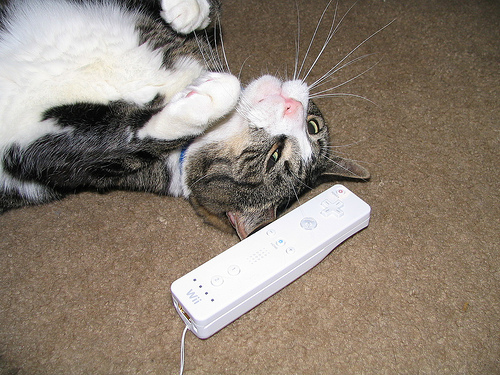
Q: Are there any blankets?
A: No, there are no blankets.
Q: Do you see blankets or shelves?
A: No, there are no blankets or shelves.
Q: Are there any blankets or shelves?
A: No, there are no blankets or shelves.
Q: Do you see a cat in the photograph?
A: Yes, there is a cat.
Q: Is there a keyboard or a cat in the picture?
A: Yes, there is a cat.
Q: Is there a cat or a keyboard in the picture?
A: Yes, there is a cat.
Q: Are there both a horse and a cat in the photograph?
A: No, there is a cat but no horses.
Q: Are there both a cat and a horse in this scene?
A: No, there is a cat but no horses.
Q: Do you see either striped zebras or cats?
A: Yes, there is a striped cat.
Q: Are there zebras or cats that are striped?
A: Yes, the cat is striped.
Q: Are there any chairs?
A: No, there are no chairs.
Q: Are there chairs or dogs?
A: No, there are no chairs or dogs.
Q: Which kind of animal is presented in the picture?
A: The animal is a cat.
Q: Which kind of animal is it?
A: The animal is a cat.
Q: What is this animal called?
A: That is a cat.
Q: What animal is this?
A: That is a cat.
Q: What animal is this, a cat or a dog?
A: That is a cat.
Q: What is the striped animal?
A: The animal is a cat.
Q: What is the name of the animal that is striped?
A: The animal is a cat.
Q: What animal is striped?
A: The animal is a cat.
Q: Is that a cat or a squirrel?
A: That is a cat.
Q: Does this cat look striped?
A: Yes, the cat is striped.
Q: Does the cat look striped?
A: Yes, the cat is striped.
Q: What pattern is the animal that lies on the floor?
A: The cat is striped.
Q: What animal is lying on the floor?
A: The cat is lying on the floor.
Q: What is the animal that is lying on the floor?
A: The animal is a cat.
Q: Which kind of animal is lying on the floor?
A: The animal is a cat.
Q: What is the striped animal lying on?
A: The cat is lying on the floor.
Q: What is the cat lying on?
A: The cat is lying on the floor.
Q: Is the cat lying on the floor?
A: Yes, the cat is lying on the floor.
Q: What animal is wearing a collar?
A: The cat is wearing a collar.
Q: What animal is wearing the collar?
A: The cat is wearing a collar.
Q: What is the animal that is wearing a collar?
A: The animal is a cat.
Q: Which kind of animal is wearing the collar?
A: The animal is a cat.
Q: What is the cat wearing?
A: The cat is wearing a collar.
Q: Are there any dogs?
A: No, there are no dogs.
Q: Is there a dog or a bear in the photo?
A: No, there are no dogs or bears.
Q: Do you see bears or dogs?
A: No, there are no dogs or bears.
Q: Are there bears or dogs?
A: No, there are no dogs or bears.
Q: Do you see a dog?
A: No, there are no dogs.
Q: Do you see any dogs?
A: No, there are no dogs.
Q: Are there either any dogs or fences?
A: No, there are no dogs or fences.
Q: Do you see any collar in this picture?
A: Yes, there is a collar.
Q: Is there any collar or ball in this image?
A: Yes, there is a collar.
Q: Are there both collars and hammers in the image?
A: No, there is a collar but no hammers.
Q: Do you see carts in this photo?
A: No, there are no carts.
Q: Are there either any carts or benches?
A: No, there are no carts or benches.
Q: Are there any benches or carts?
A: No, there are no carts or benches.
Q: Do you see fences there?
A: No, there are no fences.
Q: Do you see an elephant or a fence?
A: No, there are no fences or elephants.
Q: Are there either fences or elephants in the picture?
A: No, there are no fences or elephants.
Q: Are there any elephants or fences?
A: No, there are no fences or elephants.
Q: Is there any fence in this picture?
A: No, there are no fences.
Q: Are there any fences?
A: No, there are no fences.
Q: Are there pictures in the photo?
A: No, there are no pictures.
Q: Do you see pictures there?
A: No, there are no pictures.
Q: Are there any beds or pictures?
A: No, there are no pictures or beds.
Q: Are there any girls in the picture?
A: No, there are no girls.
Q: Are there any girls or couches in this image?
A: No, there are no girls or couches.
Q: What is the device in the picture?
A: The device is a controller.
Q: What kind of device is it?
A: The device is a controller.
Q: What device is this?
A: This is a controller.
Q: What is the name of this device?
A: This is a controller.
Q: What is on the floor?
A: The controller is on the floor.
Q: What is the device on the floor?
A: The device is a controller.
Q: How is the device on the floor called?
A: The device is a controller.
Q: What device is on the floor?
A: The device is a controller.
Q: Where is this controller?
A: The controller is on the floor.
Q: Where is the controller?
A: The controller is on the floor.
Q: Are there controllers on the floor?
A: Yes, there is a controller on the floor.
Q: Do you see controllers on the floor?
A: Yes, there is a controller on the floor.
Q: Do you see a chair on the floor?
A: No, there is a controller on the floor.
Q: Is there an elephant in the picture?
A: No, there are no elephants.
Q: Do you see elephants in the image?
A: No, there are no elephants.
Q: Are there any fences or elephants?
A: No, there are no elephants or fences.